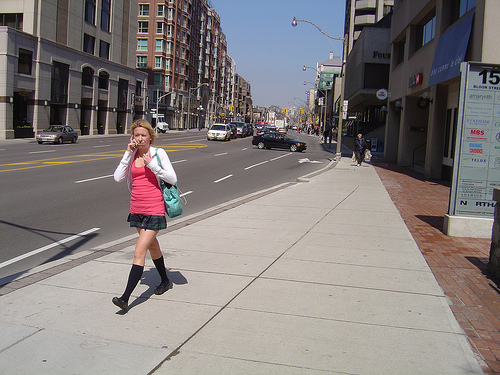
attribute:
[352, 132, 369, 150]
jacket — black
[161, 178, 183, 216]
bag — large, turquoise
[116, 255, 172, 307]
socks — long, Black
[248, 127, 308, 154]
car — black, turning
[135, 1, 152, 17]
window — rectangle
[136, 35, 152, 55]
window — rectangle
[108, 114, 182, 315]
woman — blonde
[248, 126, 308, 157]
car — black, sideways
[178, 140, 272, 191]
street — gray, dark